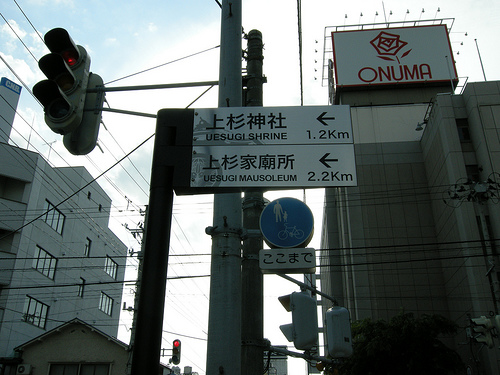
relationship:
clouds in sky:
[128, 1, 465, 121] [0, 9, 495, 358]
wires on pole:
[268, 239, 462, 310] [166, 61, 267, 246]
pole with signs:
[130, 104, 185, 374] [183, 99, 360, 197]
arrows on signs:
[315, 111, 345, 175] [194, 96, 343, 196]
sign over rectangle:
[255, 194, 313, 251] [259, 247, 320, 268]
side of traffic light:
[296, 282, 319, 343] [279, 287, 320, 349]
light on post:
[170, 337, 180, 364] [209, 3, 243, 363]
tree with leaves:
[354, 318, 455, 368] [401, 314, 428, 341]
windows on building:
[21, 198, 118, 331] [0, 78, 131, 364]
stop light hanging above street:
[33, 27, 91, 135] [5, 227, 496, 370]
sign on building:
[333, 19, 458, 92] [320, 78, 498, 373]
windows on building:
[17, 194, 123, 329] [0, 78, 131, 364]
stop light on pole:
[33, 27, 91, 135] [98, 80, 226, 92]